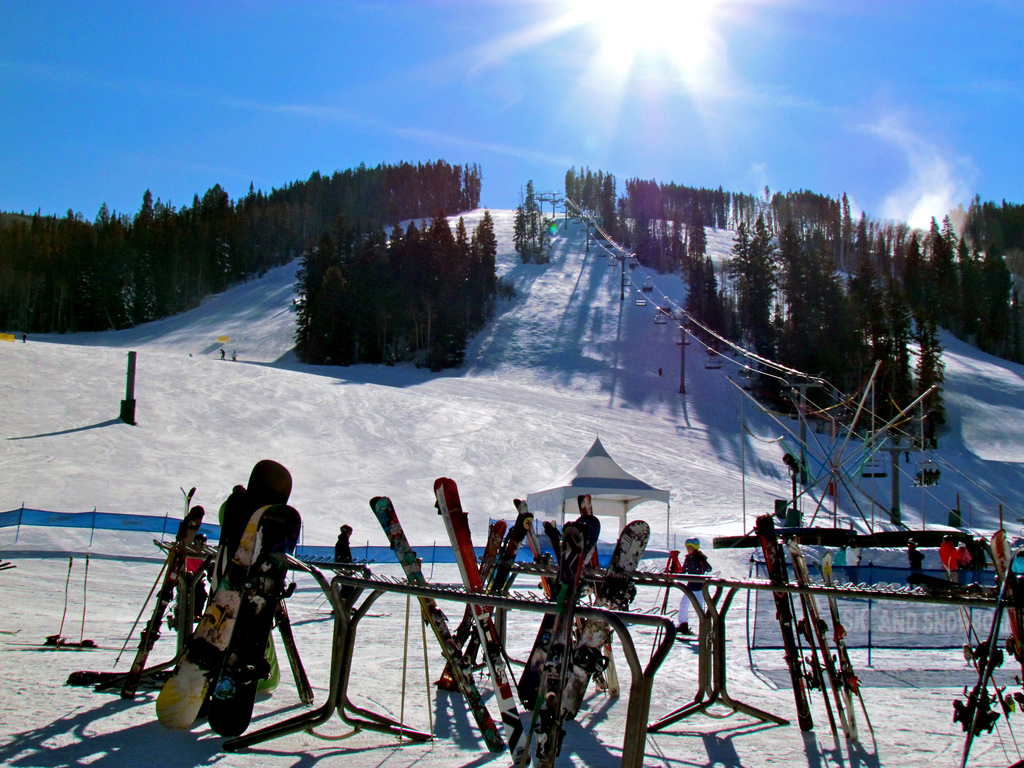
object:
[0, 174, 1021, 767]
mountain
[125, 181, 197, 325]
tree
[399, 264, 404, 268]
leaves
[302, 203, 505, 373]
tree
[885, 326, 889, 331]
leaves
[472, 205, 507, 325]
tree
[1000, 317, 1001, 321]
leaves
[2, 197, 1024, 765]
snow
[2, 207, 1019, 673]
slope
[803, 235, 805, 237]
leaf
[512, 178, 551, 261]
tree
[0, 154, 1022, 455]
field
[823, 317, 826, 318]
leaves